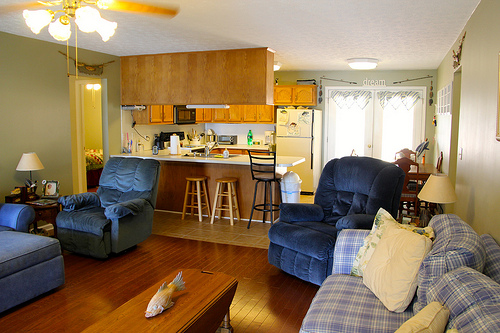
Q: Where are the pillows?
A: On the couch.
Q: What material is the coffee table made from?
A: Wood.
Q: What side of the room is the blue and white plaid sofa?
A: The right.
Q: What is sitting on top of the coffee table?
A: A fish.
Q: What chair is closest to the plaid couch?
A: A blue recliner.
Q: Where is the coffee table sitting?
A: On the floor.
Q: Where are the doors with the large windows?
A: Beside the kitchen.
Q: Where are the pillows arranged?
A: On the couch.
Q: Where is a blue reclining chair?
A: In a living room.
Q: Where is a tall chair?
A: On front a counter.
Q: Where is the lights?
A: On the ceiling.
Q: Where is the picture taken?
A: A living room.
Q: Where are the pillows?
A: On couch.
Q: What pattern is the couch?
A: Plaid.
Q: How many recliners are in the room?
A: Two.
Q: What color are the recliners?
A: Blue.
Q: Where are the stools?
A: Under the bar.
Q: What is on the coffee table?
A: A fish.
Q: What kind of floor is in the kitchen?
A: Tile.